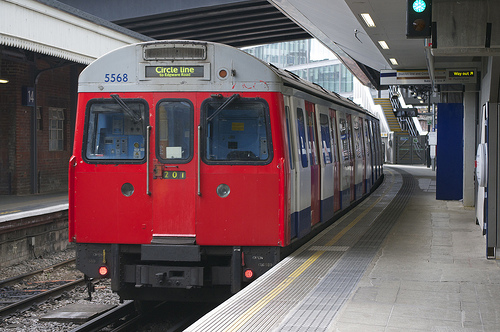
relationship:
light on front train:
[83, 250, 122, 287] [62, 40, 383, 301]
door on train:
[150, 91, 198, 247] [62, 40, 383, 301]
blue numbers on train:
[103, 72, 129, 82] [62, 37, 383, 300]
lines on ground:
[222, 250, 326, 330] [327, 258, 498, 318]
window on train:
[153, 95, 195, 167] [62, 40, 383, 301]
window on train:
[82, 94, 154, 164] [62, 40, 383, 301]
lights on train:
[213, 65, 229, 84] [66, 62, 360, 292]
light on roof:
[406, 0, 432, 37] [267, 1, 497, 103]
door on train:
[140, 91, 218, 252] [15, 21, 433, 329]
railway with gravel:
[0, 254, 158, 332] [20, 227, 236, 329]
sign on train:
[451, 68, 478, 80] [62, 40, 383, 301]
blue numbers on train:
[103, 72, 129, 82] [62, 40, 383, 301]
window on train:
[294, 102, 310, 169] [62, 40, 383, 301]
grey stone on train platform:
[346, 162, 498, 329] [186, 0, 497, 329]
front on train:
[59, 33, 296, 277] [62, 40, 383, 301]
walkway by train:
[180, 162, 495, 328] [62, 40, 383, 301]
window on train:
[196, 83, 279, 175] [72, 22, 383, 296]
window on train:
[289, 96, 313, 178] [62, 40, 383, 301]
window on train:
[319, 111, 336, 163] [62, 40, 383, 301]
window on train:
[339, 115, 350, 158] [62, 40, 383, 301]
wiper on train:
[102, 90, 147, 135] [62, 40, 383, 301]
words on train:
[153, 62, 196, 76] [62, 40, 383, 301]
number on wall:
[21, 78, 46, 115] [11, 63, 71, 205]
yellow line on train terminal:
[222, 192, 382, 329] [311, 32, 497, 330]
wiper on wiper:
[194, 90, 243, 132] [106, 87, 146, 129]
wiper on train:
[194, 90, 243, 132] [62, 40, 383, 301]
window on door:
[153, 95, 195, 167] [150, 91, 198, 247]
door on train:
[150, 91, 198, 247] [87, 59, 405, 245]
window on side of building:
[48, 101, 73, 146] [4, 43, 77, 214]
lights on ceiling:
[357, 8, 398, 70] [269, 5, 496, 97]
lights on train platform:
[357, 8, 398, 70] [170, 41, 498, 326]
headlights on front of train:
[119, 177, 232, 202] [54, 31, 419, 310]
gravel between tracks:
[3, 240, 126, 329] [0, 268, 95, 308]